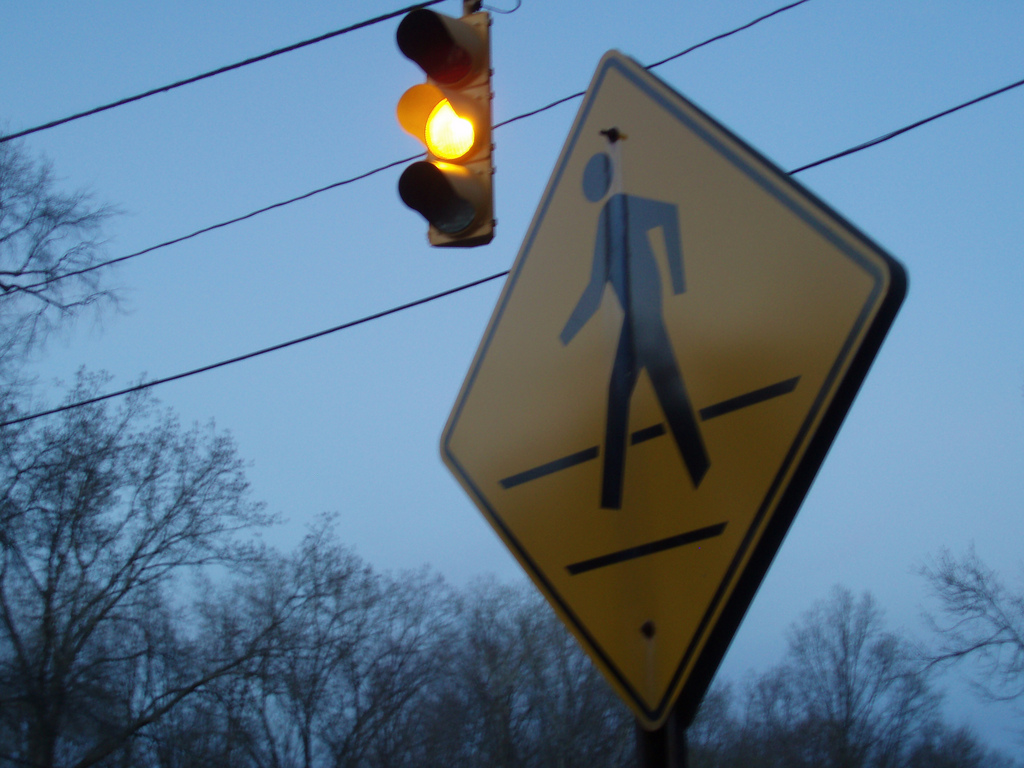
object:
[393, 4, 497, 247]
stop light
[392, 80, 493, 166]
traffic light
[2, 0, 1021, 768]
sky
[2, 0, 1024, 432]
power lines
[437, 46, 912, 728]
sign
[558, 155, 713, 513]
stick figure ma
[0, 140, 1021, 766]
trees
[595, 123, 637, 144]
bolt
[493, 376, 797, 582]
lies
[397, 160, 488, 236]
gree light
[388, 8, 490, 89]
red light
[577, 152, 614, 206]
drawig of head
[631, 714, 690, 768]
pole